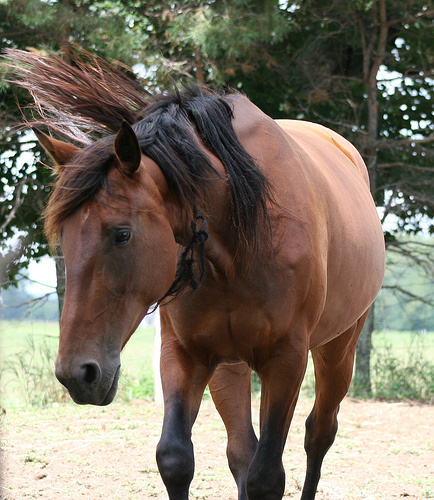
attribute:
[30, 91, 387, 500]
horse — trotting, brown, wild, serious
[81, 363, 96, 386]
nostril — dark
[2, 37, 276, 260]
mane — blowing, brown, black, wavy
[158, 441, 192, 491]
knee — black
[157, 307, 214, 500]
leg — black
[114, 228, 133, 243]
eye — soulful, small, brown, black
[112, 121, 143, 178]
ear — cute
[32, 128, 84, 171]
ear — brown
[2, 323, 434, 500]
ground — dirt, dry, dirty, brown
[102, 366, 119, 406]
mouth — black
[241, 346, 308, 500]
leg — dark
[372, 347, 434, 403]
bush — green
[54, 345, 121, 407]
snout — brown, dark, large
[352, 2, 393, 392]
tree — gray